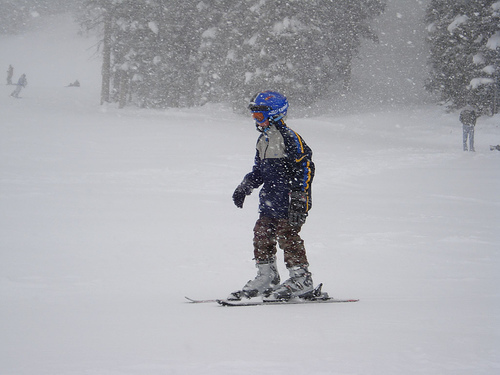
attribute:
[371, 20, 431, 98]
snow — falling, white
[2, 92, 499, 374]
ground — covered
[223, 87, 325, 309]
skier — skiing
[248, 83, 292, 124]
helmet — blue, protective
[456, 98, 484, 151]
person — looking, skiing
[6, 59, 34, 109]
skiers — coming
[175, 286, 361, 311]
skis — set, short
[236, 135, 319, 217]
arms — loose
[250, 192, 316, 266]
pants — brown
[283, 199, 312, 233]
gloves — protective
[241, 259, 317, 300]
ski boots — gray